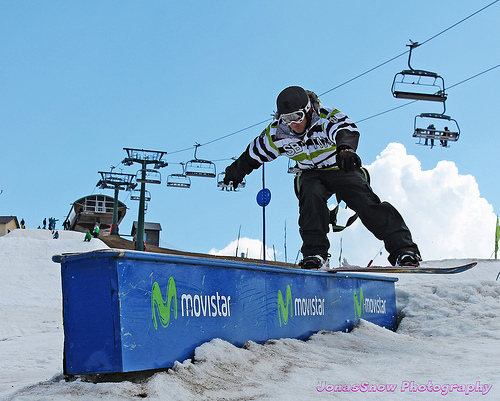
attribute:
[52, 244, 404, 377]
ramp — snowboarding ramp, blue, obstacle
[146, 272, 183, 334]
'movistar' logo — green m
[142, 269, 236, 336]
movistar+logo — repeated three times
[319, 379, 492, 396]
jonassnowphotography — logo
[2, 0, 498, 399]
photo — likely licensable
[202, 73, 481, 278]
dude — snowboarding, grinding, snowboarder, *not* skiing, man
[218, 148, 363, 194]
gloves — black, heavy, winter gloves, ski gloves maybe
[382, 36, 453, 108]
chair lift — empty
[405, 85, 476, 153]
chair lift — peopled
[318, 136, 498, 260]
cloud — white, puffy, fluffy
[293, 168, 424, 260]
pants — black, snow pants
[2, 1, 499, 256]
sky — blue, primarily clear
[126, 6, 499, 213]
chair lifts — moving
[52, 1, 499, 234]
ski lift — moving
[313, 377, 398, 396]
jonas snow — photographer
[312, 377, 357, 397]
jonas — the name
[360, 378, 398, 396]
snow — what he shoots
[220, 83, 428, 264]
snowboarder — grinding, man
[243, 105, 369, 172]
jacket — winter jacket, striped, not stripped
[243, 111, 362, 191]
stripes — green + white + blac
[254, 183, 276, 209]
sign — blue, circular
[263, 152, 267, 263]
pole — black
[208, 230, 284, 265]
cloud — small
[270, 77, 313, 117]
hat — helmetlike, black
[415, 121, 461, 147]
people — sitting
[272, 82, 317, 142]
head — human head, engaged w/ snow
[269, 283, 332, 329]
movistar — ramp company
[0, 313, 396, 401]
snow — dirty